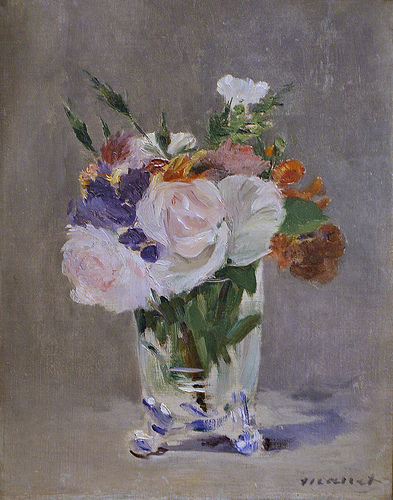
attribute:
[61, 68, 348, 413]
flowers — cluster, assorted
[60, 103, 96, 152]
leaves — green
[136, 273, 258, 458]
vase — painted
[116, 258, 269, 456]
vase — blue highlights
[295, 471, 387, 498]
name — painters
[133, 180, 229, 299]
roses — pink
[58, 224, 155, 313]
roses — pink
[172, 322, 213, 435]
stem — brown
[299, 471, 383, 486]
signature — dark lettering.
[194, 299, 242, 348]
leaves — green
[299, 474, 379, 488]
name — artist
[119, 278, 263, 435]
vase — glass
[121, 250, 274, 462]
vase —  blue and white coloring., multiple colors, clear, glass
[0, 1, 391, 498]
gray area — spots and lines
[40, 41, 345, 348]
flowers — painted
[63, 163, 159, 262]
flowers — purple, pink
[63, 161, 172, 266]
flower — purple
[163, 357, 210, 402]
light — reflected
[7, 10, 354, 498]
painting — Flower 